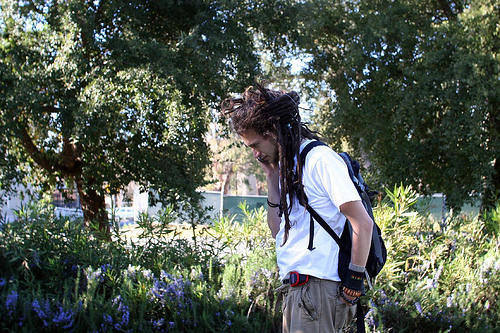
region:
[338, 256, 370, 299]
man is wearing bracelets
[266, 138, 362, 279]
man's shirt is white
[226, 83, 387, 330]
man wearing a backpack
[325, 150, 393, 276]
the backpack is blue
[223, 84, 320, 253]
man has dread locks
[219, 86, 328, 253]
man's dreads are brown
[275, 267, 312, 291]
red and black object on man's pants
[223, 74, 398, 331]
man is talking on the phone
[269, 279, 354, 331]
man's pants are brown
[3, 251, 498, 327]
purple flowers in the grass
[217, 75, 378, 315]
man near the trees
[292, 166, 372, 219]
tshirt on the man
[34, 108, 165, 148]
shaded part of tree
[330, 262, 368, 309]
glove on the hand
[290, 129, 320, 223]
straps on the shoulder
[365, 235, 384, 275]
backpack on the back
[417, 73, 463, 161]
leaves on the tree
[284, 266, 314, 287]
belt on the waist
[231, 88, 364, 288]
man wearing white t-shirt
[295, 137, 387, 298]
man carrying black backpack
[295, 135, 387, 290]
backpack is black and grey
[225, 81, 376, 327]
person using a cellphone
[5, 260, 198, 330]
blue flowers in field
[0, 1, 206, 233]
tall tree covered with leaves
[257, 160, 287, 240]
man wearing a bracelet around his arm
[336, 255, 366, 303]
man wearing dark colored glove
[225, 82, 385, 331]
person wearing grey pants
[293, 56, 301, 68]
patch of blue sky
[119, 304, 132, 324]
blue bonnet flowers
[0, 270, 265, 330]
layer of plants with blue/purple flowers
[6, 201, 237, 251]
overgrown hedge of plants in background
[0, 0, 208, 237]
tree with branches and leaves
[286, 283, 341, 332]
cargo shorts for covering skin from the waist down to the knees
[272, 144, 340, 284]
white tee shirt for torso coverage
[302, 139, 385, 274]
black and gray backpack for hauling items around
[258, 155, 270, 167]
mobile divide to ear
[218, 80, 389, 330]
person standing idly, talking on phone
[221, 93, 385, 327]
a man with dreads talking on the phone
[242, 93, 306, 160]
the dreadlocks of a man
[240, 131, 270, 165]
the face of a man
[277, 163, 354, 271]
a mans white polo shirt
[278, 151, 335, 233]
the black straps of a backpack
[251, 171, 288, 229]
the arm of a man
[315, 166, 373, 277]
the left arm of a man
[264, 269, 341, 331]
the pants of a man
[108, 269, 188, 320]
blue flowers blooming in a patch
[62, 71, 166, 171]
a bunch of dark green leaves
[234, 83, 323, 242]
man has long hair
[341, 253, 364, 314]
man is wearing bracelets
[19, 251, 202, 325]
flowers are purple in color